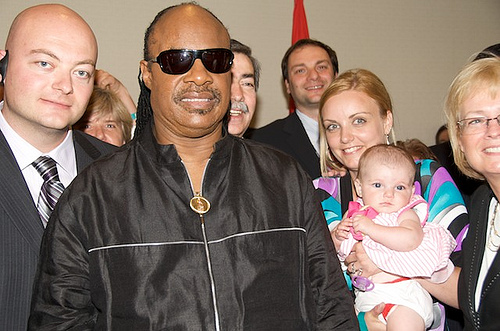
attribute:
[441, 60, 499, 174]
hair — blond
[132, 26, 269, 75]
sunglasses — black